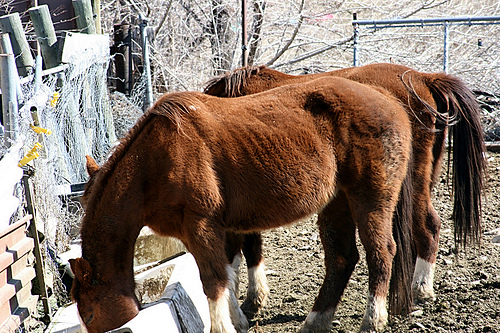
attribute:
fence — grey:
[310, 25, 405, 60]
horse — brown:
[48, 75, 408, 331]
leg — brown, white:
[344, 149, 404, 331]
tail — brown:
[390, 143, 417, 314]